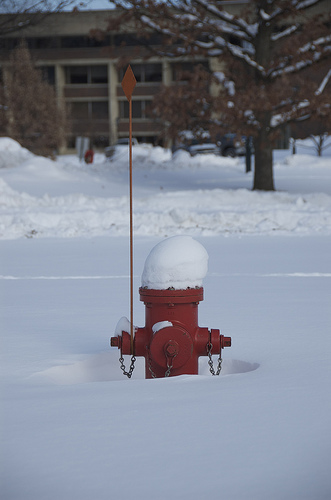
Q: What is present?
A: A hydrant.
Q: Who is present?
A: Nobody.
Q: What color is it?
A: Red.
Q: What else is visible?
A: Snow.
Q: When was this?
A: Daytime.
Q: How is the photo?
A: Clear.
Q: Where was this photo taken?
A: On a street.